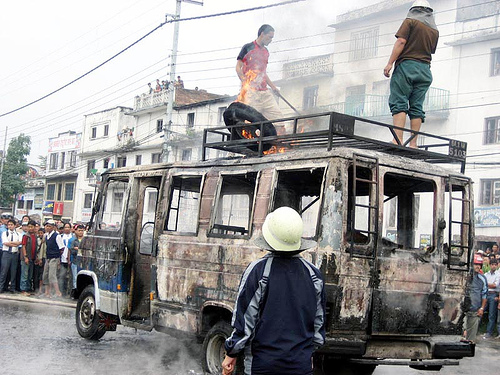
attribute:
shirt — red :
[396, 17, 439, 63]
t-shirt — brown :
[394, 17, 438, 62]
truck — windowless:
[112, 147, 446, 358]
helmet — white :
[259, 203, 306, 255]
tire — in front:
[67, 269, 146, 341]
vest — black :
[42, 231, 60, 260]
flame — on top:
[230, 61, 257, 109]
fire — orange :
[228, 66, 288, 150]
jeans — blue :
[17, 259, 33, 292]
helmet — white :
[262, 204, 302, 258]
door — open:
[124, 170, 158, 329]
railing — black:
[225, 105, 434, 162]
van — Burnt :
[71, 145, 475, 371]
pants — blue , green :
[389, 59, 431, 122]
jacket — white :
[227, 256, 329, 361]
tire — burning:
[222, 97, 278, 149]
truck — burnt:
[70, 109, 476, 374]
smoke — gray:
[282, 8, 373, 117]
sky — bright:
[0, 0, 381, 168]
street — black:
[2, 285, 498, 372]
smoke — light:
[12, 5, 495, 365]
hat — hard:
[260, 204, 305, 254]